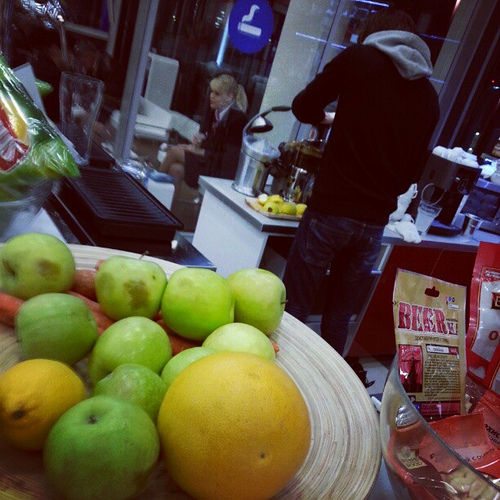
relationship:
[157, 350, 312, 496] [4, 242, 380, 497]
orange on plate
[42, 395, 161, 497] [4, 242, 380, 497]
apple on plate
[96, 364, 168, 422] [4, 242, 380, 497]
apple on plate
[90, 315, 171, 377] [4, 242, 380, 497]
apple on plate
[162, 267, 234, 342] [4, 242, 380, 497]
apple on plate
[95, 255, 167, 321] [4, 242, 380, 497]
apple on plate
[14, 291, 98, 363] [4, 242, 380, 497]
apple on plate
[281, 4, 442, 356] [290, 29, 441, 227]
man wearing sweatshirt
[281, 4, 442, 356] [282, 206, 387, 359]
man has jeans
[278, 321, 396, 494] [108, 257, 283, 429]
plate of fruit